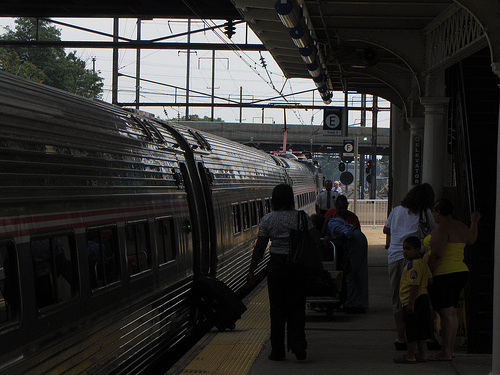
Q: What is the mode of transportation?
A: Train.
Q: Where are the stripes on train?
A: Above windows.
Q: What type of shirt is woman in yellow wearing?
A: Tube top.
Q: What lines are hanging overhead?
A: Utility.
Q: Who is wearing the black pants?
A: Woman with dark hair.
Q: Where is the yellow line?
A: On the pavement.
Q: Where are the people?
A: At the train stop.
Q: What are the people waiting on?
A: Their train.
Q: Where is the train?
A: Parked on the track.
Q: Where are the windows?
A: On the side of the train.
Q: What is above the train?
A: Metal scaffolding.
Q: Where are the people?
A: On the platform.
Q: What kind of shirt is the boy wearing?
A: Yellow shirt.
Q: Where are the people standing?
A: On the platform.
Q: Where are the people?
A: A train station.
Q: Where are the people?
A: On the platform.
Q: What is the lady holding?
A: A bag.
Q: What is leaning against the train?
A: A suitcase.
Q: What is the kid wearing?
A: A yellow shirt.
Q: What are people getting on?
A: A train.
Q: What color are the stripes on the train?
A: Red and white.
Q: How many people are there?
A: Eight.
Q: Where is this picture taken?
A: A train station.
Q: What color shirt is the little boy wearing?
A: Yellow.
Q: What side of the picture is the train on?
A: The left side.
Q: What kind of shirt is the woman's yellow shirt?
A: Strapless.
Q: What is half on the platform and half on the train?
A: A suitcase.